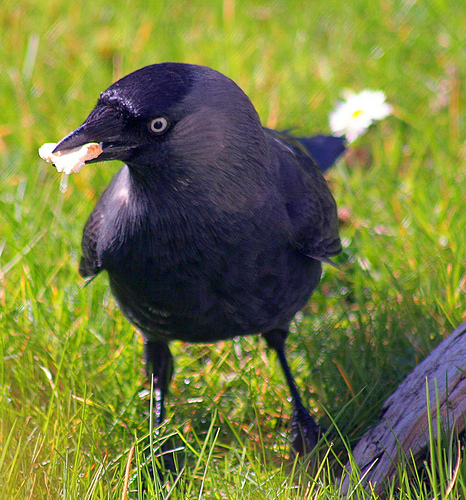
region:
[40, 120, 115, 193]
piece of bread in beak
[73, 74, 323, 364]
black bird holding something in its beak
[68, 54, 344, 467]
raven with black feathers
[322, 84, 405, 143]
white flower in the grass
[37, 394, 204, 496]
blades of green grass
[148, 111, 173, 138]
white and black eye of bird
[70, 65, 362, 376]
black bird standing on grass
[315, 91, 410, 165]
white daisy and grass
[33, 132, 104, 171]
piece of white bread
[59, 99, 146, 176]
black beak of bird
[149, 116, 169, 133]
The gray and black eye of a bird.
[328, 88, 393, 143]
A white and yellow daisy.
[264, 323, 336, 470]
A birds leg on the right.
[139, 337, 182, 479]
A birds leg on the left.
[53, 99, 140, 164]
The black beak on a bird.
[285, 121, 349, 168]
Black tailfeathers on a bird.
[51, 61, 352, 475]
A black bird with silver eyes.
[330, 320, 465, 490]
Part of a tree branch on the ground.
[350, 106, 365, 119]
The yellow center of a daisy.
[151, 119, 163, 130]
The black inside of a birds eye.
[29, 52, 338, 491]
a black bird eating a piece of bread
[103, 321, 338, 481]
a pair of black bird feet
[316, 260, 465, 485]
a log on the ground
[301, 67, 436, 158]
a daisy in a field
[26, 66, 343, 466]
a bird standing in a field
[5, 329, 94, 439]
a grassy field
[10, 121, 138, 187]
a piece of bread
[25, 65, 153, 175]
a black bird beak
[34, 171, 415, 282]
the wings of a black bird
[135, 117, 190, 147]
the grey eye of a black bird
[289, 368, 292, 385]
left leg of a bird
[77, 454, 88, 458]
tip of a grass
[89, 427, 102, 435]
part of a plantation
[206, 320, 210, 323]
feather of a bird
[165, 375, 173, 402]
right leg of a bird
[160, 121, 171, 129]
eye of a bird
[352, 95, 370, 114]
part of a flower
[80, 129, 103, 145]
beak of a bird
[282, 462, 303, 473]
section of grass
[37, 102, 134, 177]
black beak of black bird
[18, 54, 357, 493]
black bird holding piece of food in beak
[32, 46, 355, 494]
black bird standing in green grass field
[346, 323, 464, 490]
piece of fall tree bark in green grass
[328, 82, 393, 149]
white flower in green field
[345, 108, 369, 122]
yellow center of white flower in green field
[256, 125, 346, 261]
black feathered wing of black bird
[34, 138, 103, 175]
tan piece of food in bird's mouth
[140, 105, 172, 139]
black bird eye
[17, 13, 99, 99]
patch of blurred green grass